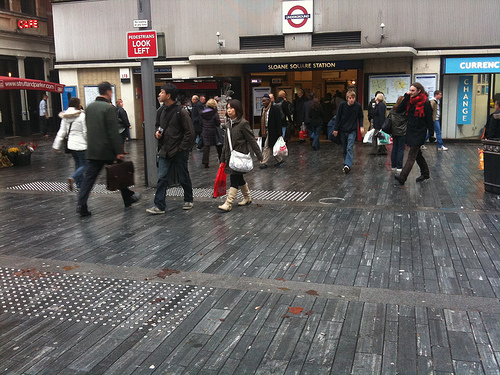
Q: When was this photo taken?
A: During the day.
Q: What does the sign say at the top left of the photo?
A: Care.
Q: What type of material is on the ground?
A: Wood.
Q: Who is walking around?
A: Men and women.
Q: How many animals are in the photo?
A: None.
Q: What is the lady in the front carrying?
A: Bag.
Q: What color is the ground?
A: Grey.